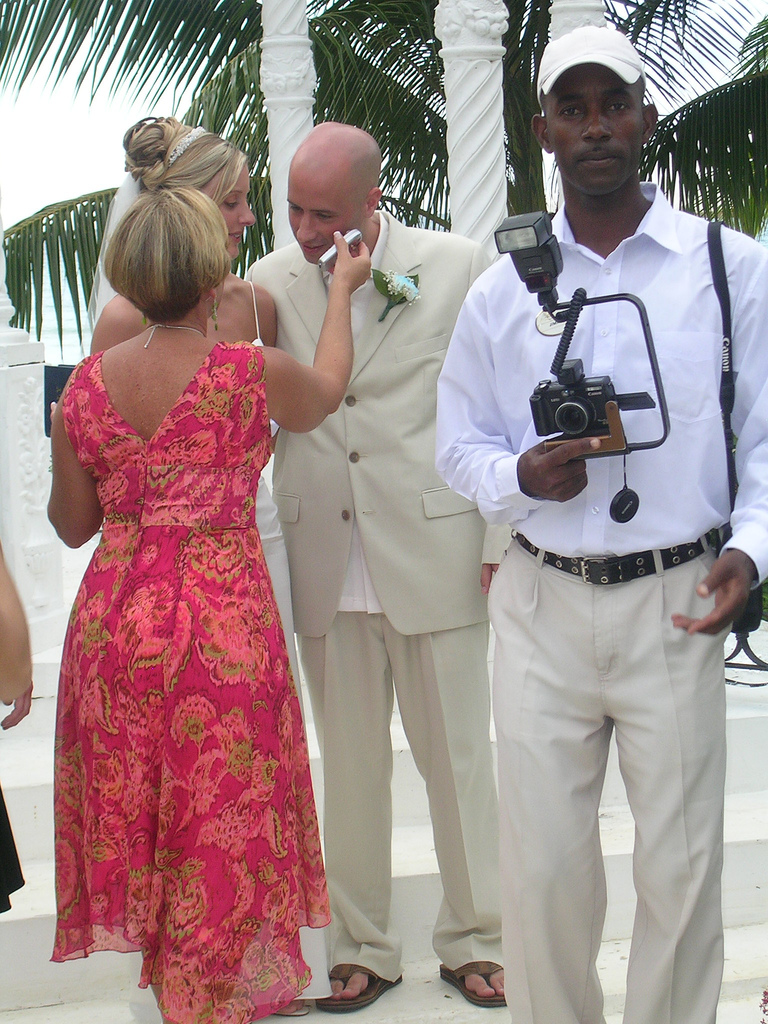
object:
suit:
[247, 206, 512, 1017]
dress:
[90, 284, 291, 1010]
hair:
[98, 183, 236, 323]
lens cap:
[608, 446, 642, 525]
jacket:
[219, 208, 490, 652]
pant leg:
[618, 580, 727, 1023]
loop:
[650, 545, 668, 580]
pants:
[493, 545, 734, 1021]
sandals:
[317, 948, 503, 1013]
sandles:
[436, 941, 509, 1010]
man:
[253, 120, 511, 1013]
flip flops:
[310, 948, 392, 1013]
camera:
[489, 205, 672, 523]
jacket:
[242, 208, 509, 635]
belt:
[506, 517, 736, 586]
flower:
[366, 263, 422, 321]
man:
[458, 50, 759, 819]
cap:
[521, 28, 663, 116]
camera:
[481, 186, 667, 529]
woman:
[0, 520, 40, 922]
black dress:
[0, 778, 22, 910]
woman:
[76, 104, 284, 608]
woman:
[40, 183, 387, 1016]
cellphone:
[314, 225, 366, 266]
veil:
[84, 169, 145, 330]